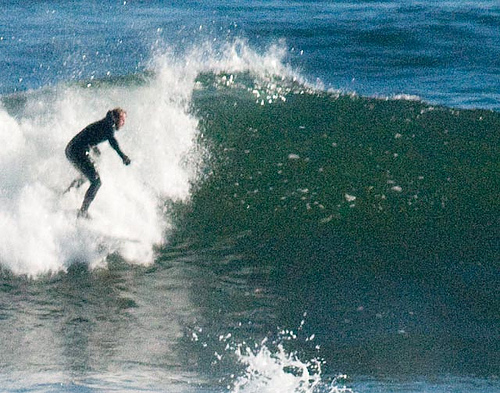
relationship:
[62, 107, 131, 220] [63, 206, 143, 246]
guy riding surfboard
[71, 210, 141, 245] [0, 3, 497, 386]
surfboard in water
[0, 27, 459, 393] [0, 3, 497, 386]
foam splashing up from water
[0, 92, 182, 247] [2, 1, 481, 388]
water wall in ocean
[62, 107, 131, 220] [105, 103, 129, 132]
guy has head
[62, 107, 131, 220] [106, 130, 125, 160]
guy has arm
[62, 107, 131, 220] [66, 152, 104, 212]
guy has leg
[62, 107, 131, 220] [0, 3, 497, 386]
guy in water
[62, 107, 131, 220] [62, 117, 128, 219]
guy in swimsuit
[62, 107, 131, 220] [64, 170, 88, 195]
guy has leg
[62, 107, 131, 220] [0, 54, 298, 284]
guy inside wave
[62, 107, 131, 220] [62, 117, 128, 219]
guy wearing swimsuit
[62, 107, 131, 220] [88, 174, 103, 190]
guy has knee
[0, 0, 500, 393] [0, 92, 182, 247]
ocean in front of water wall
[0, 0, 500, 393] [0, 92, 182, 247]
ocean curving over water wall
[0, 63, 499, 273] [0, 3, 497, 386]
water wall over water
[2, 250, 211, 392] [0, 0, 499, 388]
reflection on surface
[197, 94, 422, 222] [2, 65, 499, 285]
dots on side of wave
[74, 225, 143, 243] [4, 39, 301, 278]
surfboard in wave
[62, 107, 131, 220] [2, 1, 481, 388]
guy in ocean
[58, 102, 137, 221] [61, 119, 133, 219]
guy in swimsuit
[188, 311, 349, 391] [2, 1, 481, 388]
splash in ocean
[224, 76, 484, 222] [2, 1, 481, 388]
dots in ocean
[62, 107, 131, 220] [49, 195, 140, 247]
guy on surfboard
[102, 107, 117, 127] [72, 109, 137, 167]
hood on jacket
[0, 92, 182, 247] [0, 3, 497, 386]
water wall of water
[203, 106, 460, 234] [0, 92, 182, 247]
foam on water wall